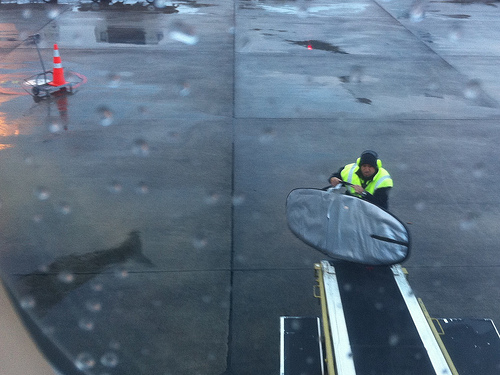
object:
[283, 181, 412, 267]
bag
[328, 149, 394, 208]
employee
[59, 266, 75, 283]
circle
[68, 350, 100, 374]
circle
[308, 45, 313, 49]
red light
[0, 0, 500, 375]
floor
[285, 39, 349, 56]
puddle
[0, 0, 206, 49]
puddle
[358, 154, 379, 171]
earmuffs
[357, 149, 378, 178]
head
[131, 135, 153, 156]
bad sentance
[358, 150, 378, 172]
cap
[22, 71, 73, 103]
dolly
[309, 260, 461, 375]
conveyor belt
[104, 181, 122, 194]
small circle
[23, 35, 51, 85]
handle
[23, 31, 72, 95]
hand cart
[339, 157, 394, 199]
coat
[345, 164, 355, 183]
reflective stripe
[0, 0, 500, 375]
paved area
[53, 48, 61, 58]
stripe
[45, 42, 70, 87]
cone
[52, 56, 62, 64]
stripe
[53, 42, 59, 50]
stripe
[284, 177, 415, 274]
circle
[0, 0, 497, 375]
water